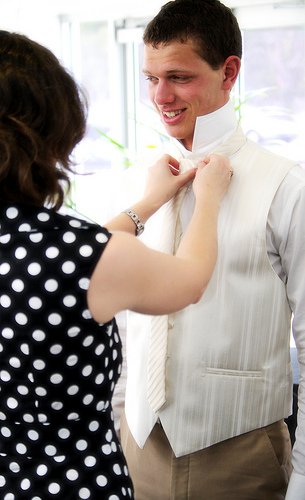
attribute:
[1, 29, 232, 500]
woman — tying, dotted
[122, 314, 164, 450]
tie — skinny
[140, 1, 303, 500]
man — smiling, dressing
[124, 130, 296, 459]
vest — stripped, sripped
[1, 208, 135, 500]
dress — polka-dotted, black, dotted, short-sleeved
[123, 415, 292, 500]
pant — khaki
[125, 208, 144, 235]
watch — silver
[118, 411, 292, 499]
pants — beige, tan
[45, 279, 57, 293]
dot — white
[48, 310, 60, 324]
dot — white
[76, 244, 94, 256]
dot — white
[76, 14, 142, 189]
window — lite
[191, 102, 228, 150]
collar — popped